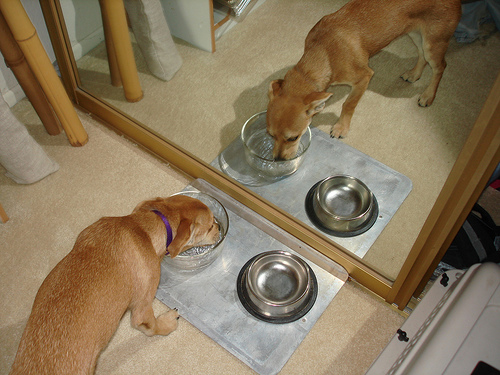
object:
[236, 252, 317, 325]
bowl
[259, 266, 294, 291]
water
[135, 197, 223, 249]
head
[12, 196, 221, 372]
dog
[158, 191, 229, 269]
bowl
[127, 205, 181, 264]
neck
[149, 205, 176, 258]
collar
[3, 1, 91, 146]
bamboo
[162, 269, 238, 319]
matt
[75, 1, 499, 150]
mirror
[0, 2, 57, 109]
wall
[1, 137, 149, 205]
floor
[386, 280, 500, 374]
crate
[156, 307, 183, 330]
claw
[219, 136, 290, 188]
light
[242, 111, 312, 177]
glass bowl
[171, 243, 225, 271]
water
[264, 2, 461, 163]
dog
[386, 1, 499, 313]
frame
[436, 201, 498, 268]
travel bag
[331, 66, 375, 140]
leg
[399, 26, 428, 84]
leg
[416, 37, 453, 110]
leg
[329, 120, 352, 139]
paw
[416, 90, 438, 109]
paw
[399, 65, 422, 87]
paw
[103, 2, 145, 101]
pillar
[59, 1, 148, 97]
corner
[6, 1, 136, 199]
corner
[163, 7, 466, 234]
reflection